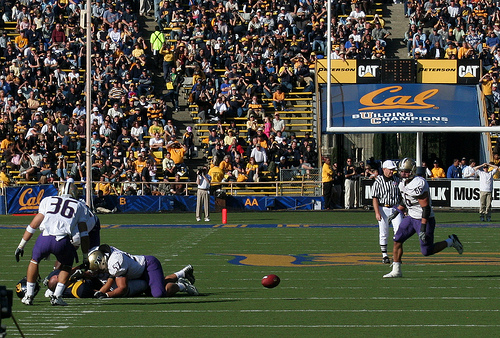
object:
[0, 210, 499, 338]
field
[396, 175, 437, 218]
shrit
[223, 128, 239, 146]
people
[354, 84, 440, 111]
sign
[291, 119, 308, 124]
seats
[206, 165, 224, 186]
shirt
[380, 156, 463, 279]
player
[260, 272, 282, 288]
football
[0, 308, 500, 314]
lines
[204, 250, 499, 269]
logo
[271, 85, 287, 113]
fans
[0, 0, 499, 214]
bleachers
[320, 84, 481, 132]
awning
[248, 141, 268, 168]
coaches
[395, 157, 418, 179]
helmet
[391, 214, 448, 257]
pants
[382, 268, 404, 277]
shoes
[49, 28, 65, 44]
shirts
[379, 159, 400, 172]
cap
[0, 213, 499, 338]
ground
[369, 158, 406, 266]
referee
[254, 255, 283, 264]
paint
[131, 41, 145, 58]
spectators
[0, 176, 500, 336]
game